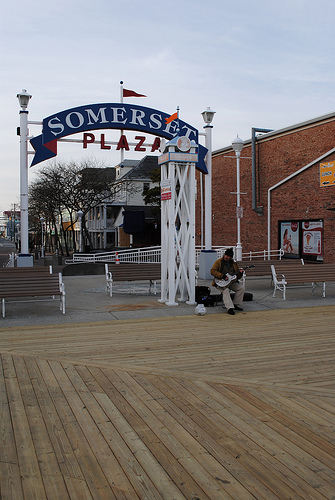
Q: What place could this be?
A: It is a sidewalk.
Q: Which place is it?
A: It is a sidewalk.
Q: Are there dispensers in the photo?
A: No, there are no dispensers.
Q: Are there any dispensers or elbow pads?
A: No, there are no dispensers or elbow pads.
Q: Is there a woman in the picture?
A: No, there are no women.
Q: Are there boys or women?
A: No, there are no women or boys.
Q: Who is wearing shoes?
A: The man is wearing shoes.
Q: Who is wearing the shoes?
A: The man is wearing shoes.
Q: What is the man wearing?
A: The man is wearing shoes.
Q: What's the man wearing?
A: The man is wearing shoes.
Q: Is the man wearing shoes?
A: Yes, the man is wearing shoes.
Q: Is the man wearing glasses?
A: No, the man is wearing shoes.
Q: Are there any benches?
A: Yes, there is a bench.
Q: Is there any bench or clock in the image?
A: Yes, there is a bench.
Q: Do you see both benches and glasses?
A: No, there is a bench but no glasses.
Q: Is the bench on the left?
A: Yes, the bench is on the left of the image.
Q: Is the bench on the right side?
A: No, the bench is on the left of the image.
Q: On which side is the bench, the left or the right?
A: The bench is on the left of the image.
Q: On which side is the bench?
A: The bench is on the left of the image.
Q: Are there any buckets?
A: No, there are no buckets.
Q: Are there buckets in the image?
A: No, there are no buckets.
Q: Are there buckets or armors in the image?
A: No, there are no buckets or armors.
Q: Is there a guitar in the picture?
A: Yes, there is a guitar.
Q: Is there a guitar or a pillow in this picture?
A: Yes, there is a guitar.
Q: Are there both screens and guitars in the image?
A: No, there is a guitar but no screens.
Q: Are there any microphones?
A: No, there are no microphones.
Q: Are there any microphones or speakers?
A: No, there are no microphones or speakers.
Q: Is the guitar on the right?
A: Yes, the guitar is on the right of the image.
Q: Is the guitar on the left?
A: No, the guitar is on the right of the image.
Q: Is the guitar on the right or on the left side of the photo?
A: The guitar is on the right of the image.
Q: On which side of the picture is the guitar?
A: The guitar is on the right of the image.